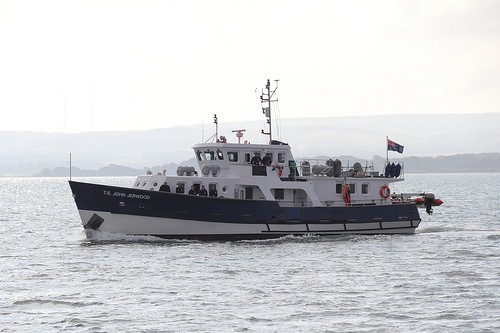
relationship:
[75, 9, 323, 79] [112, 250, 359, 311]
bright light over ocean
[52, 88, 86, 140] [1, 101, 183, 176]
poles outlined over mountain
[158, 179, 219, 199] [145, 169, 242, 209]
people on side of windows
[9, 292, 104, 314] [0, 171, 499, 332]
wave in water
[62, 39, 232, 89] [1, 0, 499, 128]
cloud in sky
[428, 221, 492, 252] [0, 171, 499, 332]
ripples in water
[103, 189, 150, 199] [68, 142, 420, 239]
letters on boat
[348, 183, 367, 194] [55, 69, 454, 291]
window on boat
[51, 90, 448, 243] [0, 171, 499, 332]
boat in water